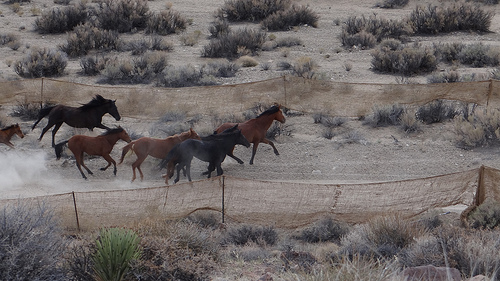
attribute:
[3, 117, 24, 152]
horse — brown, running, fast, wild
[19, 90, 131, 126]
horse — brown, running, fast, wild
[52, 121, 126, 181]
horse — brown, running, fast, wild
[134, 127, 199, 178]
horse — brown, running, fast, wild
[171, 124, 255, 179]
horse — brown, running, fast, wild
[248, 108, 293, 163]
horse — brown, running, fast, wild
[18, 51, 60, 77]
bush — green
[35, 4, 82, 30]
bush — green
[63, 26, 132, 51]
bush — green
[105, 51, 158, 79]
bush — green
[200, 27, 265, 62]
bush — green, flowering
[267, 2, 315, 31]
bush — green, flowering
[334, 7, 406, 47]
bush — green, flowering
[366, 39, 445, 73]
bush — green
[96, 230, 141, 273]
bush — flowering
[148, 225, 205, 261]
bush — green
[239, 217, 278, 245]
bush — green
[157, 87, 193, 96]
net — brown